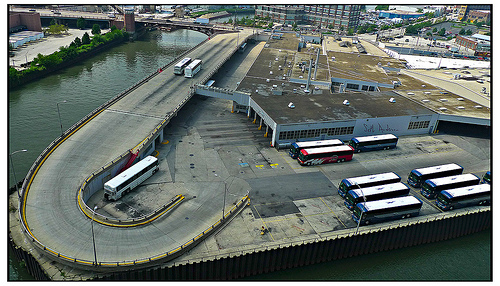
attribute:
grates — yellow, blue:
[232, 148, 272, 173]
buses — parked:
[342, 173, 466, 211]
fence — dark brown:
[8, 177, 490, 280]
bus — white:
[92, 136, 187, 221]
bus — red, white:
[297, 144, 354, 167]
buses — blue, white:
[308, 157, 488, 223]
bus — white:
[103, 152, 158, 199]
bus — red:
[293, 140, 353, 168]